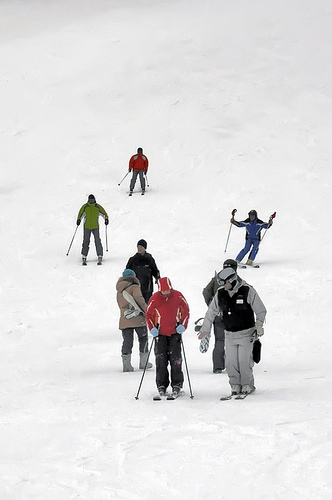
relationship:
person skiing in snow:
[68, 193, 112, 266] [3, 1, 329, 500]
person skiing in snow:
[220, 206, 276, 263] [3, 1, 329, 500]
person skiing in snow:
[125, 151, 152, 194] [3, 1, 329, 500]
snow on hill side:
[3, 1, 329, 500] [1, 3, 331, 270]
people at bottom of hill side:
[115, 237, 272, 407] [1, 3, 331, 270]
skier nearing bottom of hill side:
[220, 206, 276, 263] [1, 3, 331, 270]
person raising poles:
[220, 206, 276, 263] [219, 211, 274, 247]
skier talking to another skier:
[141, 279, 192, 399] [202, 277, 265, 401]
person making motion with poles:
[220, 206, 276, 263] [219, 211, 274, 247]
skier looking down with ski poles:
[141, 279, 192, 399] [135, 330, 199, 401]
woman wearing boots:
[110, 266, 150, 370] [122, 351, 154, 375]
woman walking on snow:
[110, 266, 150, 370] [3, 1, 329, 500]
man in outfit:
[125, 239, 161, 298] [126, 252, 162, 296]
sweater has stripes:
[143, 276, 190, 332] [147, 279, 191, 326]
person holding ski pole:
[220, 206, 276, 263] [221, 212, 236, 250]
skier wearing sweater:
[141, 279, 192, 399] [143, 276, 190, 332]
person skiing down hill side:
[68, 193, 112, 266] [1, 3, 331, 270]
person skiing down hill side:
[220, 206, 276, 263] [1, 3, 331, 270]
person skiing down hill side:
[125, 151, 152, 194] [1, 3, 331, 270]